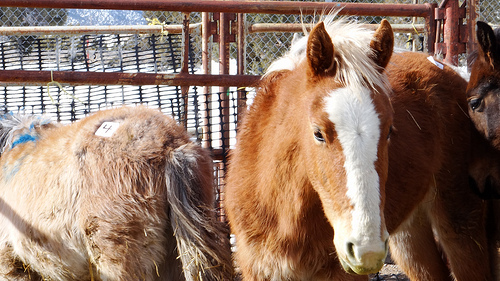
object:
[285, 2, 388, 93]
mane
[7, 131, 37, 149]
spot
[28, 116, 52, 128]
spot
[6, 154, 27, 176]
spot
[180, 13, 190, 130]
pole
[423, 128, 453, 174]
ground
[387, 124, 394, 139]
eye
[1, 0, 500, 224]
rail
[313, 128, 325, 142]
eye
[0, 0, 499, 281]
winter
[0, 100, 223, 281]
animal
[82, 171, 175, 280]
leg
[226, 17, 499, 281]
horse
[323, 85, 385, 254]
patch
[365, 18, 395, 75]
ear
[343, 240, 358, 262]
nostril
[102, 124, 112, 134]
4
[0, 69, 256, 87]
pole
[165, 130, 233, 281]
tail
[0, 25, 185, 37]
pipe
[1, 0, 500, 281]
fence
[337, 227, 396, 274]
nose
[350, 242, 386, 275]
tip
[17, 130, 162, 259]
fur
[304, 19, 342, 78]
ears